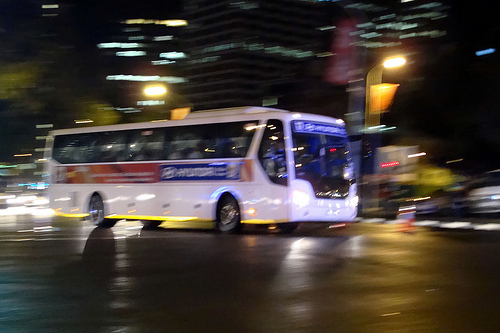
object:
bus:
[42, 105, 360, 237]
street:
[1, 215, 499, 331]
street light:
[382, 54, 407, 69]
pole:
[363, 64, 379, 220]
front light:
[293, 190, 309, 208]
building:
[179, 3, 345, 123]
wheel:
[217, 194, 244, 234]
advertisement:
[51, 160, 253, 185]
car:
[453, 169, 499, 217]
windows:
[54, 120, 259, 165]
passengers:
[73, 139, 235, 163]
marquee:
[293, 120, 348, 137]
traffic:
[1, 194, 53, 223]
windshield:
[291, 121, 356, 200]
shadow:
[52, 228, 351, 331]